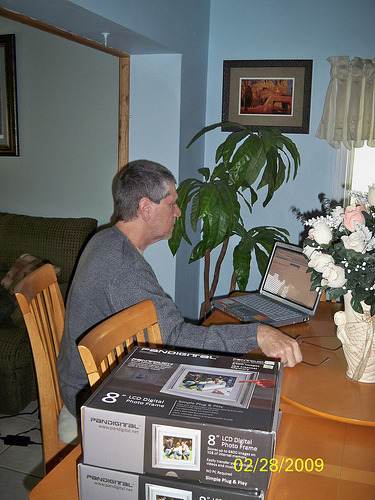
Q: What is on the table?
A: Flowers.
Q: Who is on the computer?
A: A man.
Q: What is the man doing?
A: He's on a computer.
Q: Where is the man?
A: In a dining room.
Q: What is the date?
A: 02/28/2009.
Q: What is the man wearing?
A: A sweater.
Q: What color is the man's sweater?
A: Gray.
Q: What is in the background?
A: A plant.